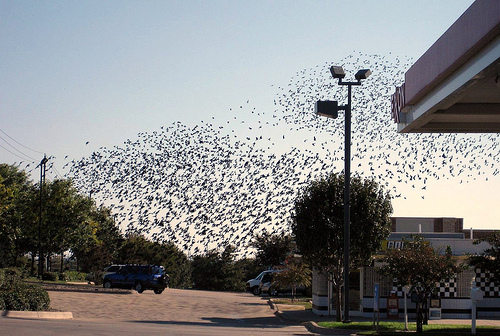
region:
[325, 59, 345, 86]
Large black and clear light on a post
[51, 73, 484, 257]
Large flock of birds flying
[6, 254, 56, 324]
Large shrub on the pavement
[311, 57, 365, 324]
Tall black light post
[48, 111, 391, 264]
A group of birds are taking flight.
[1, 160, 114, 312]
The trees have leaves on the left side.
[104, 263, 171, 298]
There is a blue SUV parked.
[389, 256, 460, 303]
There is a black and white checkered wall on the restaurant.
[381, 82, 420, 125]
There is a sign for a exxon gas station.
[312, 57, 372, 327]
There is a street light in front the gas station.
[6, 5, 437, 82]
The sky is cloudless.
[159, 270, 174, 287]
The SUV has a spare tire on the back.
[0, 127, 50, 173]
There are power lines next to the trees.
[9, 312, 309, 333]
There is a paved roadway in the picture.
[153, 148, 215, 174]
the birds are black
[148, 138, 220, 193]
birds in the sky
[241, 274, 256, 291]
a white van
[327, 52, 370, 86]
a street light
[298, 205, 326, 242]
the tree is round and green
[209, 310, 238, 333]
a shadow on the street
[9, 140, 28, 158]
electrical lines in the sky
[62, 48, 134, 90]
the sky is clear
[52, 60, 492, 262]
flock of flying birds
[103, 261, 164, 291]
suv in parking lot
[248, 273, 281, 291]
white van in parking lot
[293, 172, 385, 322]
tree next to building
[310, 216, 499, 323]
building in the parking lot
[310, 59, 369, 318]
parking lot light fixture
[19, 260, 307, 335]
parking lot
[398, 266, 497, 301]
black and white checks on building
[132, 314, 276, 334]
shadow on the parking lot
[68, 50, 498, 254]
large flock of birds in sky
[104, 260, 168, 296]
Blue vehicle in parking lot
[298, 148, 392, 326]
tree near pole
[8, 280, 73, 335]
bushes on median strip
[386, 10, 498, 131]
roof over hanging lot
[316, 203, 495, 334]
building behind tree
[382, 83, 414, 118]
letter in the overhanging roof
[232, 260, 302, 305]
cars parking in lot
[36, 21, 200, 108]
blue sky above land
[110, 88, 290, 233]
birds in the air